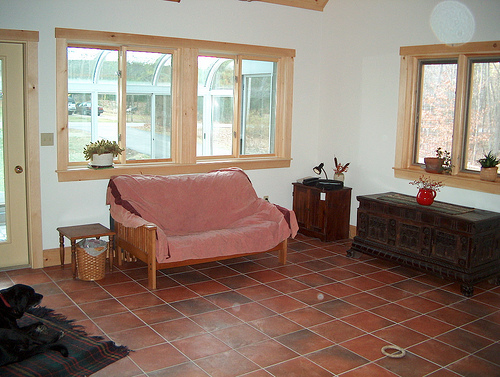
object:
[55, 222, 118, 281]
table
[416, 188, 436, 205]
pot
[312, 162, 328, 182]
lamp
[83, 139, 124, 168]
plant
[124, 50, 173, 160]
window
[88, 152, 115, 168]
pot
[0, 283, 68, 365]
dog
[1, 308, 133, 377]
blanket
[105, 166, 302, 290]
couch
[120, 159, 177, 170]
edge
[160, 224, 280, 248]
edge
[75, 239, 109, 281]
bin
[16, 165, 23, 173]
knob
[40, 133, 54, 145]
switch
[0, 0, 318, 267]
wall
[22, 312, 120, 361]
stripes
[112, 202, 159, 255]
arms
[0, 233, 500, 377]
floor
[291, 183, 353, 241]
chest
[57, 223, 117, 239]
top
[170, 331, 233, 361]
tiles